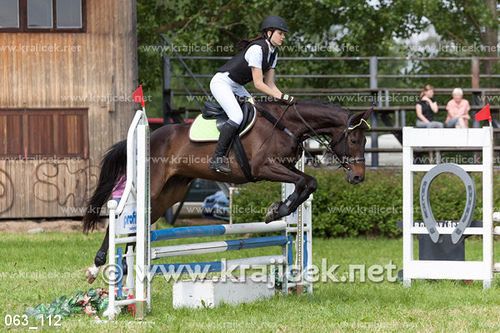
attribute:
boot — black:
[209, 112, 246, 177]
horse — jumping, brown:
[82, 102, 377, 287]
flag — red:
[131, 85, 146, 105]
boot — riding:
[214, 117, 226, 167]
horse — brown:
[69, 94, 378, 282]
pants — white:
[206, 54, 278, 120]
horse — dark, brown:
[71, 5, 380, 287]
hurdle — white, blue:
[92, 102, 326, 324]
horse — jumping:
[81, 80, 391, 229]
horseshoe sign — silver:
[418, 160, 475, 246]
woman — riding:
[207, 12, 287, 177]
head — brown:
[325, 100, 373, 188]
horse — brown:
[81, 95, 368, 302]